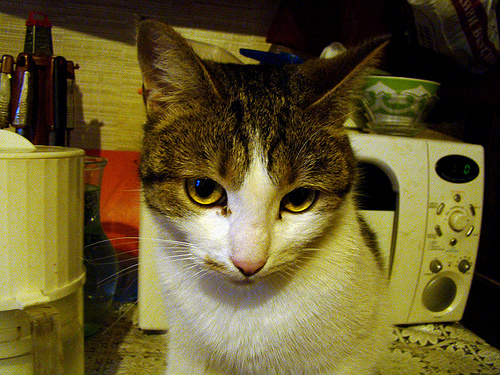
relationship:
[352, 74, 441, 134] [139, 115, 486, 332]
green bowl stacked on microwave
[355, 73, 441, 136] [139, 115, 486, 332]
glass bowl stacked on microwave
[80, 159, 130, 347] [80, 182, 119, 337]
vase with liquid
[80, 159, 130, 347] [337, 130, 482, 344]
vase next to microwave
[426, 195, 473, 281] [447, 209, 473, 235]
buttons and dial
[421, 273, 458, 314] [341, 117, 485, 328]
button on microwave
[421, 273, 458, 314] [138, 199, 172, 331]
button on microwave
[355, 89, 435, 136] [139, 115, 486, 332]
glass bowl on microwave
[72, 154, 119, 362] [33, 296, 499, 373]
vase on countertop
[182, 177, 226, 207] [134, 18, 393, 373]
eye of cat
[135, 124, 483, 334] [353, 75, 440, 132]
microwave oven in bowl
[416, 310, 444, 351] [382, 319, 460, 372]
table cloth with flowers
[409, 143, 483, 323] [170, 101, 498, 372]
control button of microwave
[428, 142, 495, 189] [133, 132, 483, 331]
display of microwave